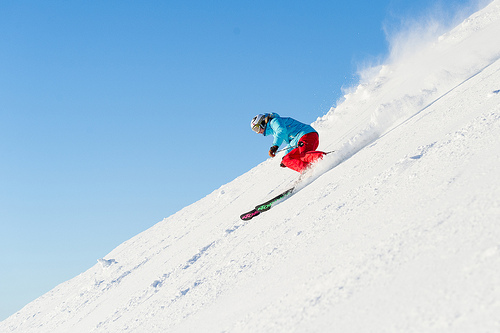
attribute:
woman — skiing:
[248, 110, 330, 181]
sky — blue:
[258, 32, 348, 66]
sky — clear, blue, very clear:
[0, 0, 494, 323]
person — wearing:
[245, 107, 340, 182]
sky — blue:
[1, 4, 206, 195]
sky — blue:
[44, 113, 128, 167]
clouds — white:
[13, 115, 128, 191]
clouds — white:
[3, 133, 63, 201]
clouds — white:
[15, 207, 79, 246]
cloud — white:
[0, 127, 144, 317]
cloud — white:
[0, 126, 188, 315]